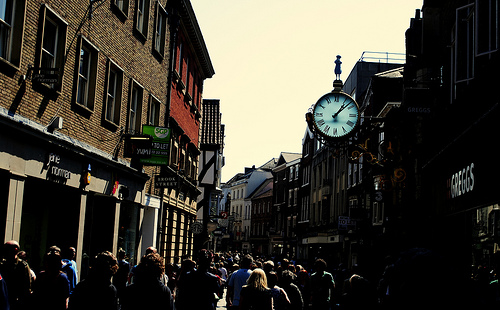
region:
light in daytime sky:
[192, 2, 421, 169]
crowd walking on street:
[25, 243, 358, 308]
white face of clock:
[312, 90, 359, 137]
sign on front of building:
[448, 163, 476, 198]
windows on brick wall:
[4, 1, 163, 143]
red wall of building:
[161, 40, 206, 175]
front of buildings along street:
[230, 146, 394, 258]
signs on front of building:
[132, 126, 180, 194]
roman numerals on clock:
[316, 95, 357, 137]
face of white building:
[230, 183, 252, 235]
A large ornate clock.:
[303, 55, 385, 173]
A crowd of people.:
[1, 246, 394, 308]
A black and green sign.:
[138, 121, 173, 166]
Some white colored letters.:
[448, 163, 478, 200]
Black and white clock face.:
[311, 93, 358, 136]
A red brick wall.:
[164, 37, 203, 203]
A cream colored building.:
[229, 179, 255, 237]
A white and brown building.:
[192, 96, 219, 226]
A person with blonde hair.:
[239, 266, 271, 308]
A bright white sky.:
[188, 1, 423, 182]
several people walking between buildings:
[17, 205, 451, 307]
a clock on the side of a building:
[309, 50, 413, 160]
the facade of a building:
[231, 184, 256, 247]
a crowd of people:
[210, 251, 290, 305]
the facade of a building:
[248, 183, 273, 253]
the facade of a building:
[308, 145, 338, 246]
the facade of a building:
[1, 0, 175, 261]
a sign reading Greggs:
[441, 162, 493, 203]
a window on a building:
[73, 30, 101, 117]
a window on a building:
[40, 3, 65, 94]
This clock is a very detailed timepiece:
[326, 75, 358, 137]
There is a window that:
[78, 33, 101, 113]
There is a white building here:
[233, 177, 247, 229]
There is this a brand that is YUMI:
[134, 143, 154, 170]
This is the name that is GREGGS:
[443, 170, 483, 207]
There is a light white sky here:
[266, 55, 281, 107]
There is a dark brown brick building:
[273, 188, 290, 233]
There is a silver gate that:
[377, 44, 383, 68]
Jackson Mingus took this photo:
[149, 34, 276, 271]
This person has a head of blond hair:
[255, 273, 265, 300]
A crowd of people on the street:
[2, 237, 364, 307]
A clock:
[306, 55, 383, 155]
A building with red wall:
[161, 0, 216, 264]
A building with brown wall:
[0, 0, 172, 282]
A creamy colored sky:
[189, 0, 426, 186]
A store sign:
[450, 162, 475, 198]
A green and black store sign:
[139, 122, 171, 164]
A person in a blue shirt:
[64, 244, 79, 285]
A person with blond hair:
[242, 269, 272, 309]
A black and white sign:
[151, 171, 180, 189]